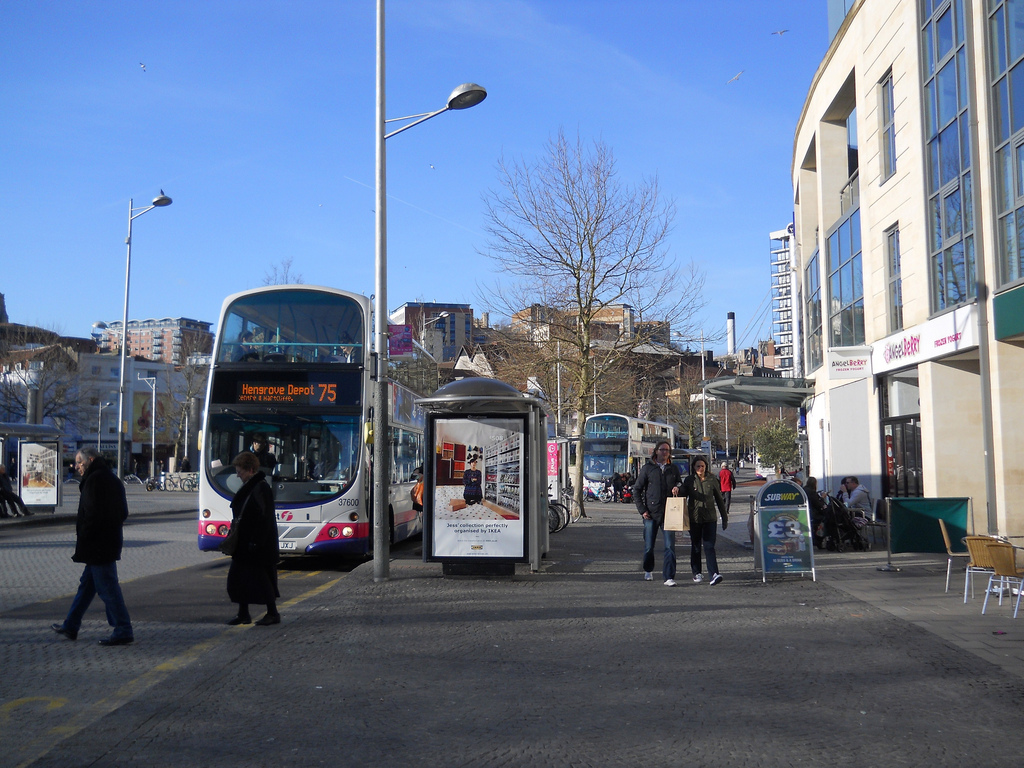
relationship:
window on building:
[860, 70, 924, 189] [783, 69, 991, 471]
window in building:
[860, 70, 924, 189] [783, 69, 991, 471]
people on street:
[632, 441, 724, 575] [565, 560, 672, 745]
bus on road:
[223, 305, 392, 579] [128, 488, 195, 606]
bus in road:
[223, 305, 392, 579] [128, 488, 195, 606]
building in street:
[783, 69, 991, 471] [565, 560, 672, 745]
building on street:
[783, 69, 991, 471] [565, 560, 672, 745]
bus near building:
[223, 305, 392, 579] [783, 69, 991, 471]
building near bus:
[783, 69, 991, 471] [223, 305, 392, 579]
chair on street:
[924, 517, 1009, 627] [565, 560, 672, 745]